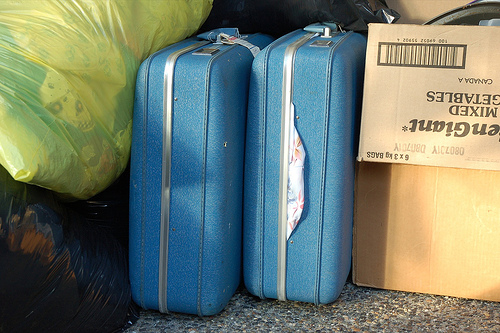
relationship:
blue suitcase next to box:
[124, 27, 273, 317] [352, 19, 499, 304]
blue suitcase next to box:
[242, 20, 366, 306] [352, 19, 499, 304]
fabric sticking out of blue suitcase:
[285, 103, 305, 240] [242, 20, 366, 306]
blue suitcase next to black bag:
[124, 27, 273, 317] [0, 165, 142, 333]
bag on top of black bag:
[0, 0, 214, 201] [2, 180, 141, 327]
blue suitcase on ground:
[242, 20, 366, 306] [131, 279, 498, 331]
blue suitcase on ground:
[124, 27, 273, 317] [130, 284, 498, 330]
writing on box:
[366, 36, 500, 166] [352, 19, 499, 304]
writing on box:
[366, 36, 500, 166] [353, 20, 498, 169]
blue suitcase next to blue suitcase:
[124, 27, 273, 317] [242, 20, 366, 306]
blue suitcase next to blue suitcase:
[242, 20, 366, 306] [124, 27, 273, 317]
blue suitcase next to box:
[128, 27, 271, 321] [352, 19, 499, 304]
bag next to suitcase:
[4, 4, 107, 193] [115, 14, 240, 317]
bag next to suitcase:
[4, 4, 107, 193] [241, 18, 366, 308]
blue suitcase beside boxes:
[242, 20, 366, 306] [366, 22, 498, 314]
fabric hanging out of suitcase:
[282, 101, 306, 239] [241, 18, 366, 308]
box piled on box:
[353, 20, 498, 169] [352, 157, 499, 306]